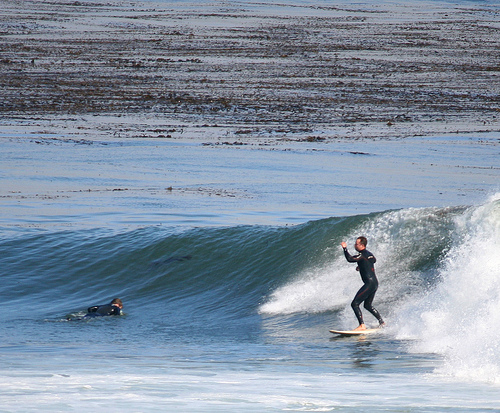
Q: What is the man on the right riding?
A: A surfboard.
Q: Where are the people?
A: In the ocean.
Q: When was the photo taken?
A: Daytime.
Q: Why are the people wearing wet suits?
A: They're surfing.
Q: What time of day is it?
A: Afternoon.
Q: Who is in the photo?
A: Two surfers.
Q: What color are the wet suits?
A: Black.